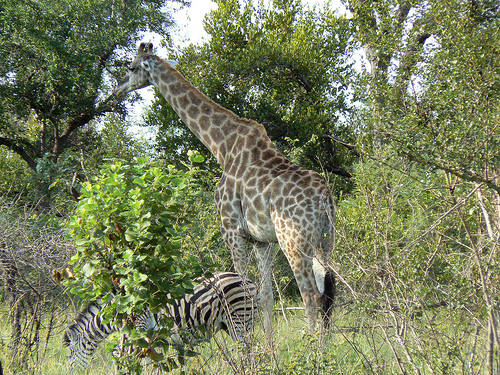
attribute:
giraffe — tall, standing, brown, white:
[114, 41, 343, 340]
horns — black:
[136, 42, 155, 57]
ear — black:
[140, 61, 153, 72]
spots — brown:
[219, 155, 325, 225]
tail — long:
[325, 185, 337, 318]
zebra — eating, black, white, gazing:
[57, 270, 260, 375]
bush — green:
[55, 149, 223, 375]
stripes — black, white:
[170, 272, 257, 336]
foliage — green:
[1, 150, 500, 374]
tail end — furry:
[320, 272, 336, 325]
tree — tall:
[139, 2, 353, 190]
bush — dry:
[0, 177, 80, 375]